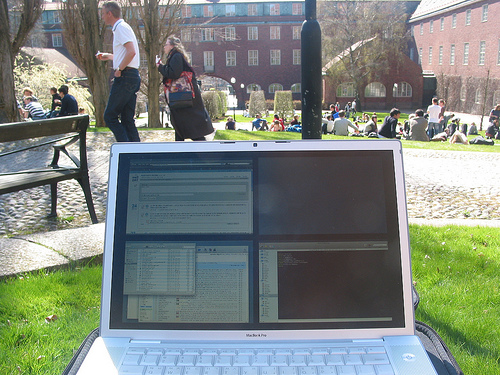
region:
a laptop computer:
[86, 130, 406, 372]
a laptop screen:
[108, 131, 412, 323]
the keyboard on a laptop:
[96, 340, 361, 373]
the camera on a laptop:
[241, 131, 268, 157]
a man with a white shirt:
[97, 6, 143, 141]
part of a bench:
[9, 99, 102, 223]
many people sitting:
[244, 95, 491, 144]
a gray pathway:
[435, 156, 487, 210]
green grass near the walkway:
[430, 242, 487, 314]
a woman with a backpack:
[157, 33, 214, 128]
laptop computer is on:
[68, 160, 372, 372]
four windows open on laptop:
[122, 159, 384, 327]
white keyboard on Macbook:
[86, 325, 393, 374]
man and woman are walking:
[96, 8, 239, 136]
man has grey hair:
[98, 2, 115, 15]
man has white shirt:
[111, 14, 138, 76]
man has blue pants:
[92, 68, 150, 135]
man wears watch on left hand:
[111, 63, 128, 73]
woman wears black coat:
[140, 44, 239, 156]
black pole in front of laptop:
[272, 7, 341, 124]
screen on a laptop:
[182, 180, 357, 308]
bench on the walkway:
[14, 123, 86, 221]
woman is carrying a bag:
[163, 69, 201, 113]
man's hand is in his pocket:
[102, 63, 135, 89]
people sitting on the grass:
[365, 116, 418, 146]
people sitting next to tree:
[8, 103, 60, 111]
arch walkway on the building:
[206, 65, 259, 106]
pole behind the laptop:
[259, 90, 339, 135]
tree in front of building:
[343, 72, 394, 125]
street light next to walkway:
[226, 71, 244, 94]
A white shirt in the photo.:
[105, 21, 140, 68]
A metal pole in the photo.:
[290, 26, 336, 138]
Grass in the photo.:
[2, 288, 69, 356]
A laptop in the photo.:
[112, 141, 417, 373]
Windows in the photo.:
[428, 39, 490, 71]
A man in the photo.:
[92, 2, 146, 140]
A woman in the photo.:
[154, 34, 215, 140]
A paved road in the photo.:
[414, 158, 495, 208]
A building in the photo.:
[416, 15, 492, 95]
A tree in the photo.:
[333, 2, 385, 102]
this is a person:
[92, 2, 157, 143]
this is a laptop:
[82, 137, 457, 372]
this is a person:
[147, 26, 232, 149]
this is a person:
[45, 65, 82, 128]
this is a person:
[20, 83, 54, 128]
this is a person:
[247, 100, 277, 135]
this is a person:
[332, 86, 362, 139]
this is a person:
[384, 105, 411, 140]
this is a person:
[404, 95, 425, 145]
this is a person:
[416, 95, 458, 137]